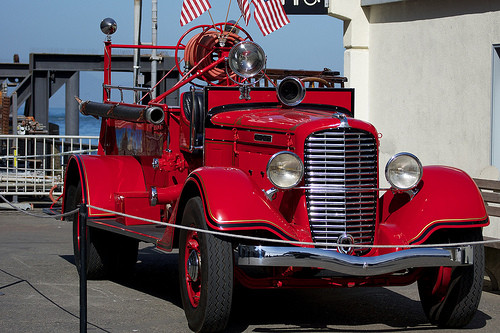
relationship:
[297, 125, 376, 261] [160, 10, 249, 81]
grill on engine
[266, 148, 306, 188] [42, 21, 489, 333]
light on front of car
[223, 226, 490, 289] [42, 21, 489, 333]
bumper on car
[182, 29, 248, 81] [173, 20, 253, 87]
hose wrapped in wheel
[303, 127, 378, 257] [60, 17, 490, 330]
grill in front of car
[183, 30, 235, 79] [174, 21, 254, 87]
hose on spool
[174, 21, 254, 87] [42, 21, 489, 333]
spool on car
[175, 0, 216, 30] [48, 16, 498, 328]
flag on engine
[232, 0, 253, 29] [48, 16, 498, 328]
flag on engine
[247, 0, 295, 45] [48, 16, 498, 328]
flag on engine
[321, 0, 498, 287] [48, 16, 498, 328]
building next engine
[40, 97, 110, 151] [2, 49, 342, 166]
water behind beams